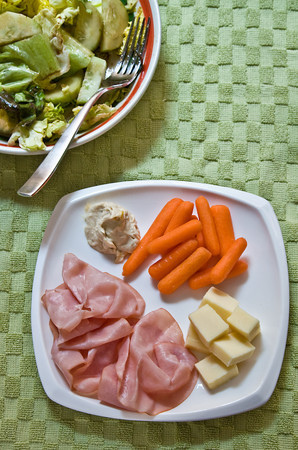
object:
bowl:
[1, 0, 162, 158]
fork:
[16, 16, 152, 198]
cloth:
[0, 0, 297, 449]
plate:
[32, 178, 291, 423]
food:
[39, 196, 263, 420]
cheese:
[189, 302, 228, 346]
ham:
[41, 252, 198, 416]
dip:
[83, 201, 139, 262]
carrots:
[214, 233, 249, 284]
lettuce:
[0, 0, 139, 150]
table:
[3, 3, 296, 446]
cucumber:
[1, 39, 46, 106]